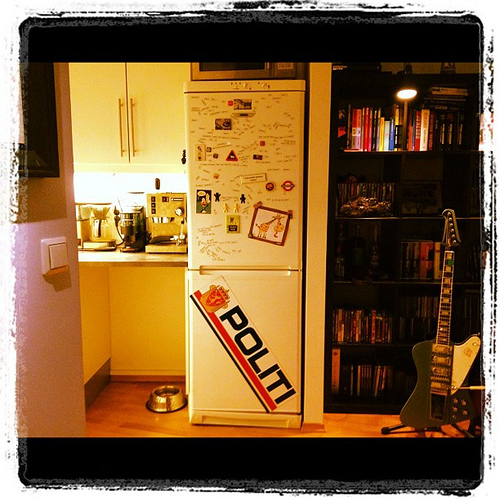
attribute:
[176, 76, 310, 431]
refrigerator — white, two door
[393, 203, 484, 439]
guitar — green, white, stand, standing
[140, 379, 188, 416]
dish — metal, silver, dog bowl, gray, water bowl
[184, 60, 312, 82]
microwave — stainless steel, silver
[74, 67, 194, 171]
cabinet — white, light wooden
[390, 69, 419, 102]
light — turned on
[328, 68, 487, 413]
bookshelf — tall, full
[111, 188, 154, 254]
coffee pot — clear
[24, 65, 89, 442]
wall — white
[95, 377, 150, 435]
floor — brown, hardwood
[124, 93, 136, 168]
handle — long